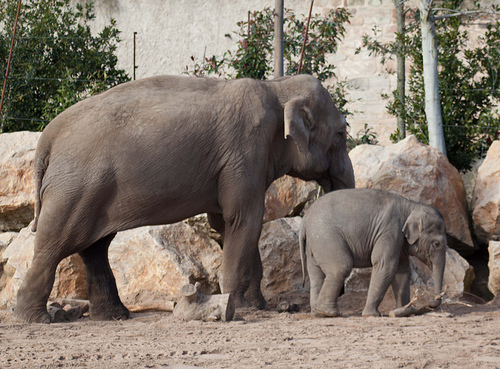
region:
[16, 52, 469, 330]
two elephants in enclosure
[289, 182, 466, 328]
paper elephant walking on dirt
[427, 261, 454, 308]
trunk of baby elephant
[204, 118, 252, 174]
wrinkles on elephant skin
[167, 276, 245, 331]
cut log on ground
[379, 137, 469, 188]
rock in zoo enclosure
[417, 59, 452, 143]
trunk of gray tree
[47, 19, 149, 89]
wires and pole of fence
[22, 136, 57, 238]
tail of adult elephant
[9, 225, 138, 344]
back legs of elephant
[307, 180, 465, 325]
Small Indian elephant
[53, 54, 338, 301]
Large Indian elephant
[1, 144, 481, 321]
large boulders behind the elephants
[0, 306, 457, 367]
Brown dirt under the elephants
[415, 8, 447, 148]
Tall white tree stump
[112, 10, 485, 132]
brick wall of the elephant enclosure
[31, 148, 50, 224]
Dangling tail of the large elephant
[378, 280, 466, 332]
Fallen branch near small elephant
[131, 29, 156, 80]
Narrow pole in background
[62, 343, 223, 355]
Tractor tire marks in dirt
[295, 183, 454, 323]
small rhinoceros on right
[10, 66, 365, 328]
larger rhoceros on left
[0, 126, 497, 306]
large stone rocks behind rhinos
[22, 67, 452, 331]
rhino on right is lighter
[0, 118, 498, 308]
tan and beige colored stones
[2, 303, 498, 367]
light brown sand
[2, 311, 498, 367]
small track marks in sand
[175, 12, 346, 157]
bush with green and red leaves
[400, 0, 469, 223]
gray tree trunk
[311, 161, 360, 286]
larger rhino's trunk behind the baby rhino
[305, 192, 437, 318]
the elephant is small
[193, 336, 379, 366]
the ground has brown dirt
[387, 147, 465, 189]
the stone is brown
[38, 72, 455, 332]
the animlas are in a zoo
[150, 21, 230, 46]
the wall is made of concrete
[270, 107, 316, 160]
the ears are flapping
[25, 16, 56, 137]
the fence is electrical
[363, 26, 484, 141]
the trees are in the background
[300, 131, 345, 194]
the elephant has no task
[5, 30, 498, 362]
the scene is outdoors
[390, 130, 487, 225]
big stones are visible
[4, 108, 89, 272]
big stones are visible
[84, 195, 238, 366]
big stones are visible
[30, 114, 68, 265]
big stones are visible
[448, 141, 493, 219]
big stones are visible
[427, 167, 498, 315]
big stones are visible